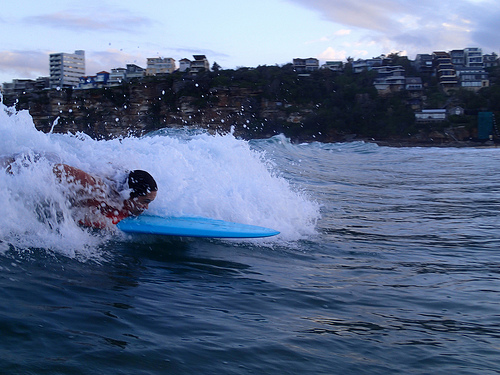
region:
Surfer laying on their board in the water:
[1, 158, 281, 238]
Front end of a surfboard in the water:
[151, 213, 283, 240]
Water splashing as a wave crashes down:
[1, 98, 324, 263]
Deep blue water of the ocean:
[13, 245, 489, 348]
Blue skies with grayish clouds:
[4, 2, 494, 70]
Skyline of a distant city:
[1, 47, 496, 110]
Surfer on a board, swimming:
[8, 156, 280, 240]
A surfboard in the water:
[142, 213, 280, 240]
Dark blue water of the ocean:
[256, 139, 498, 374]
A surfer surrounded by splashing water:
[41, 157, 153, 221]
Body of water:
[2, 69, 499, 372]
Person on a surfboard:
[0, 148, 282, 240]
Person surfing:
[0, 148, 282, 243]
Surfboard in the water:
[118, 207, 278, 239]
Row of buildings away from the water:
[0, 45, 498, 120]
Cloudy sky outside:
[0, 0, 498, 83]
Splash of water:
[0, 72, 325, 267]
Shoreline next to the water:
[0, 62, 496, 152]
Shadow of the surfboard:
[98, 237, 248, 285]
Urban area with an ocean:
[0, 0, 499, 373]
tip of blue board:
[261, 227, 282, 243]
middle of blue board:
[181, 209, 207, 248]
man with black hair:
[131, 173, 146, 185]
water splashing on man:
[73, 174, 100, 204]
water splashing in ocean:
[281, 193, 312, 235]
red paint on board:
[96, 211, 114, 223]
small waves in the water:
[298, 299, 450, 361]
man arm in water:
[53, 166, 92, 183]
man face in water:
[133, 196, 150, 212]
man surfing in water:
[1, 84, 333, 300]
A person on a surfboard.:
[4, 154, 279, 241]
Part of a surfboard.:
[213, 219, 278, 241]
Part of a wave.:
[181, 153, 240, 198]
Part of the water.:
[251, 289, 316, 346]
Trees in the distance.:
[327, 82, 364, 110]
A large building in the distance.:
[48, 48, 88, 84]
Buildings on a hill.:
[375, 66, 422, 93]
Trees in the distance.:
[218, 69, 253, 85]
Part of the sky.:
[228, 19, 285, 45]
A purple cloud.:
[1, 52, 48, 74]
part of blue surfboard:
[144, 212, 284, 238]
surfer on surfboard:
[0, 161, 176, 229]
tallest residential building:
[50, 48, 85, 86]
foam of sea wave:
[220, 154, 257, 219]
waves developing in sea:
[351, 140, 372, 153]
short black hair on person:
[130, 160, 155, 191]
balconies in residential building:
[431, 47, 459, 87]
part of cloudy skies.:
[313, 5, 429, 49]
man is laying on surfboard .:
[0, 146, 284, 247]